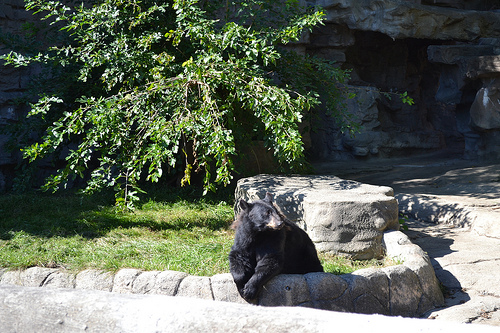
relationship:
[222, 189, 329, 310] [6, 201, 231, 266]
bear in grass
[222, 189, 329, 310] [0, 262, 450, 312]
bear on rocks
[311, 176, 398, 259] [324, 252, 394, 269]
rock on ground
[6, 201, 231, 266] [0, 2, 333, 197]
grass next tree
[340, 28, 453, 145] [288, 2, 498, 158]
cave inside rock wall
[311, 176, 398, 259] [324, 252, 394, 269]
boulders on ground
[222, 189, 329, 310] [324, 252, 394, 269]
bear sitting on ground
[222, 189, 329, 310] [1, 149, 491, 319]
bear relaxing in sun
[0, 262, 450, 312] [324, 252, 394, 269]
barrier on ground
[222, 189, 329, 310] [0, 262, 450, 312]
bear leaning over rock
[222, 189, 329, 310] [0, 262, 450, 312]
black bear standing on rock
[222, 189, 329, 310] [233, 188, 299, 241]
bear with head turned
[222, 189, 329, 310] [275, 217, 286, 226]
bear has black nose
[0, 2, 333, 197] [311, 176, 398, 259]
tree over a rock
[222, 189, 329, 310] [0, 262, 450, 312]
bear hanging over rock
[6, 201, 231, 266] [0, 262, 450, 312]
grass surrounded by stone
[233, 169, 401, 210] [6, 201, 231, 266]
platform in grass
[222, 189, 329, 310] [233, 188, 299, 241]
bear looking forward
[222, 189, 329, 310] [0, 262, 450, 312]
bear leaning on wall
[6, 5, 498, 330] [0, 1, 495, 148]
zoo has wall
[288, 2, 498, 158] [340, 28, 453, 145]
rock has opening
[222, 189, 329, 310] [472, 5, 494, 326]
bear looking right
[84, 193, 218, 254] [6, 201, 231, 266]
shadow on ground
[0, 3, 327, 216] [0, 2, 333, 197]
leaves on tree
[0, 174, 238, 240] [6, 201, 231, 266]
shadow on grass